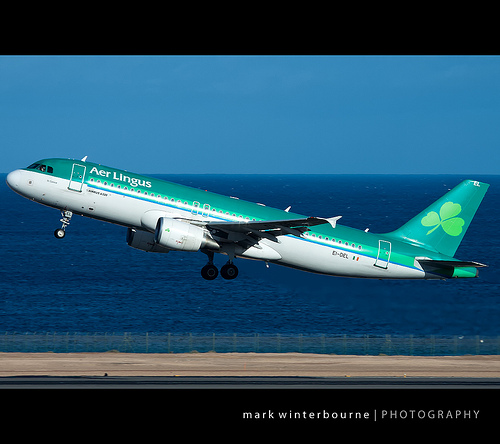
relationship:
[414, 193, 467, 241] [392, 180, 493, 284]
shamrock on tail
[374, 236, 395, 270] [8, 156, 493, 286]
door on back of plane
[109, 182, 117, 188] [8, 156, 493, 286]
window on side of plane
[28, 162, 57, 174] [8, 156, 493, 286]
window on front of plane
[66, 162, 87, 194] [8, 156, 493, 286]
door on front of plane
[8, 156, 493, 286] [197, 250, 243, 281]
plane has landing gear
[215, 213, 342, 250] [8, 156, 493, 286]
wing on side of plane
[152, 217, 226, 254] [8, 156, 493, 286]
engine attached to plane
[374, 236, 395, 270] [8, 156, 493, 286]
door on plane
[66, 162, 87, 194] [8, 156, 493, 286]
door on plane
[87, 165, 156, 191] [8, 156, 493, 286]
letters on side of plane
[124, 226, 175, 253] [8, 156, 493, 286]
engine on plane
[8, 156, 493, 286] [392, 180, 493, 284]
plane has a tail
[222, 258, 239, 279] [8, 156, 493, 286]
wheel under plane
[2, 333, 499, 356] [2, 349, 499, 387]
fence running across runway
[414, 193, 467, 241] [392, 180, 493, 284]
shamrock on planes tail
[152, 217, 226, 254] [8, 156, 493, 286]
engine on plane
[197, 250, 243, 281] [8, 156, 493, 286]
landing gear attached to plane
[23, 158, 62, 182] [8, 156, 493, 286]
cockpit of plane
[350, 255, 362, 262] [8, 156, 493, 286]
logo on belly of plane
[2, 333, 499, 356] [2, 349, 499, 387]
fence around runway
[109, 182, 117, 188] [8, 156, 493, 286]
window on front of plane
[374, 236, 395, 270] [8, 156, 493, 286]
door on side of plane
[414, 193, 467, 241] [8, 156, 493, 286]
shamrock on plane